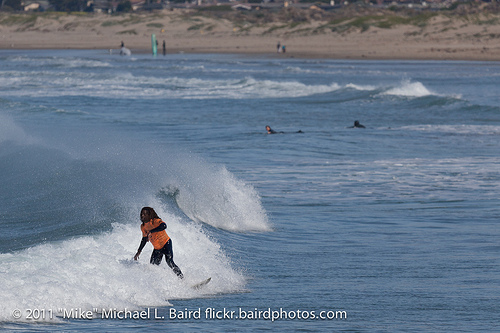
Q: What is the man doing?
A: Surfing.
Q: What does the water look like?
A: Wavy.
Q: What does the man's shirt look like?
A: Orange and short sleeve.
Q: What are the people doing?
A: Surfing.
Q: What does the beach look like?
A: Wet.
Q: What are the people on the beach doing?
A: Walking.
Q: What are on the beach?
A: Dunes.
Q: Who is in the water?
A: People.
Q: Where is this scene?
A: Ocean.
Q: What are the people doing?
A: Surfing.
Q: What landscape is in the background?
A: Dunes.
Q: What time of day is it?
A: Daytime.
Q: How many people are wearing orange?
A: One.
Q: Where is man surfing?
A: Water.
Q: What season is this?
A: Summer.